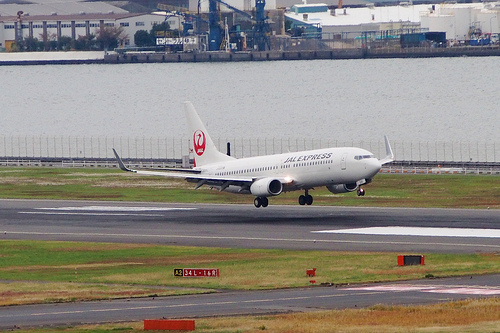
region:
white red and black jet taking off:
[111, 98, 396, 208]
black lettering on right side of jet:
[282, 151, 332, 164]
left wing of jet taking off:
[377, 132, 397, 162]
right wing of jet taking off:
[111, 145, 254, 182]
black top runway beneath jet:
[0, 196, 498, 255]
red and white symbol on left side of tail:
[192, 128, 207, 157]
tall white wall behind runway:
[1, 54, 498, 162]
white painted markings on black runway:
[17, 204, 499, 239]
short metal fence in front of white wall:
[0, 133, 498, 173]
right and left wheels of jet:
[252, 193, 314, 208]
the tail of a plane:
[177, 87, 232, 189]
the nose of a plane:
[370, 157, 387, 176]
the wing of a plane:
[108, 143, 261, 192]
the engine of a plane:
[246, 171, 287, 200]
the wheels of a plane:
[294, 188, 316, 207]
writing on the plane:
[280, 148, 335, 163]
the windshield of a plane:
[351, 152, 378, 162]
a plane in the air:
[104, 96, 407, 211]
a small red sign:
[182, 265, 226, 278]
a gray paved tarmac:
[0, 195, 499, 254]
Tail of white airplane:
[174, 90, 216, 155]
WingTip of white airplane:
[104, 142, 133, 177]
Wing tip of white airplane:
[378, 131, 401, 161]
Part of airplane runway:
[28, 221, 90, 236]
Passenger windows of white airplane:
[208, 168, 275, 173]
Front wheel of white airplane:
[353, 185, 369, 199]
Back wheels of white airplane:
[253, 197, 274, 207]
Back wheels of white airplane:
[296, 192, 318, 206]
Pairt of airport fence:
[13, 146, 72, 168]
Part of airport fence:
[421, 154, 476, 170]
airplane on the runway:
[82, 93, 400, 224]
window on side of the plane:
[327, 160, 335, 168]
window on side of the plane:
[320, 158, 327, 168]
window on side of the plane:
[301, 158, 308, 170]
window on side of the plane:
[286, 161, 290, 172]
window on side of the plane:
[286, 163, 287, 170]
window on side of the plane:
[284, 163, 288, 171]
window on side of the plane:
[268, 164, 277, 168]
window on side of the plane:
[261, 164, 268, 173]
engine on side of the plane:
[251, 177, 277, 204]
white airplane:
[145, 101, 405, 231]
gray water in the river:
[25, 76, 87, 106]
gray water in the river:
[60, 78, 118, 122]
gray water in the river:
[196, 69, 258, 111]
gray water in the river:
[266, 92, 311, 123]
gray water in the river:
[326, 65, 421, 127]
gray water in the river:
[425, 52, 479, 127]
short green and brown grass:
[15, 248, 63, 270]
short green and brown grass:
[116, 252, 151, 292]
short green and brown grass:
[235, 251, 270, 281]